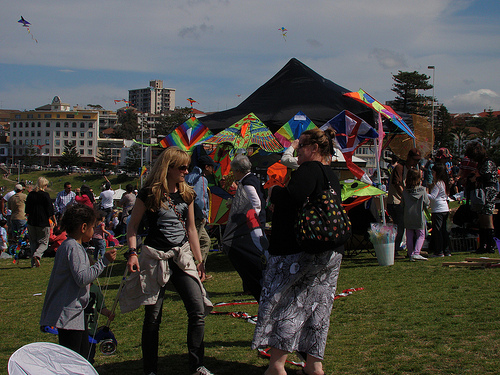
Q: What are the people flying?
A: Kites.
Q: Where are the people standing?
A: On a field.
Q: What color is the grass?
A: Green.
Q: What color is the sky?
A: Blue.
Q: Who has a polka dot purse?
A: The woman with the black top.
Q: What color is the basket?
A: White.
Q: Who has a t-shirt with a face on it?
A: The blonde woman.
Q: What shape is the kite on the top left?
A: Airplane.